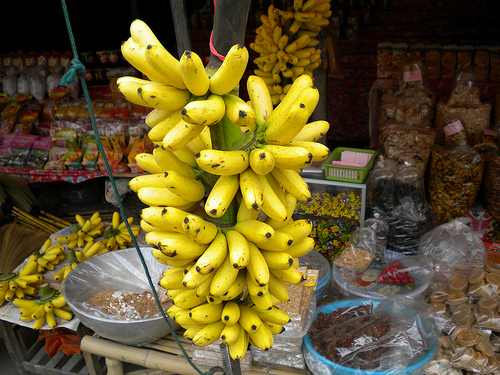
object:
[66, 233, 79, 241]
bananas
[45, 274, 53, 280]
platform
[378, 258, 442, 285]
wrappings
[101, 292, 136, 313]
spices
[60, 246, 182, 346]
bowl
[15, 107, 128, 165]
snacks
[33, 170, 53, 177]
stand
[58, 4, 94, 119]
rope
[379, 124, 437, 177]
bags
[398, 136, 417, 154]
banana peels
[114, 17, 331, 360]
bananas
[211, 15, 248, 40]
stick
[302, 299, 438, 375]
bowl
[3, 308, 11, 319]
table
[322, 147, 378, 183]
basket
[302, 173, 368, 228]
shelf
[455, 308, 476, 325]
cookies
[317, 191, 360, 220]
flowers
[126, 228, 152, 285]
cording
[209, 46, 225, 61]
rope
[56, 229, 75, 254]
display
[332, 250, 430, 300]
bowls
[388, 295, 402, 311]
plastic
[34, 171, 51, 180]
fabric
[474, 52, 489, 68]
food items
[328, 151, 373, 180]
papers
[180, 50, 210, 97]
banana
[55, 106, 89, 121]
packet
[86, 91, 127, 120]
cerals